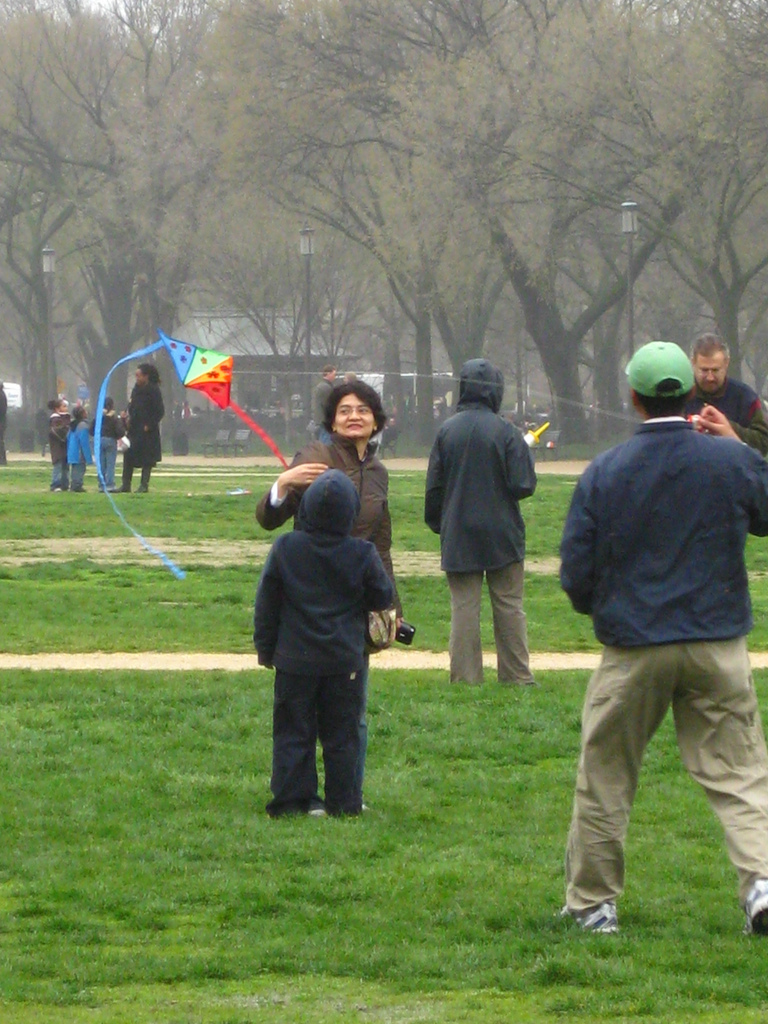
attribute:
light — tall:
[271, 184, 379, 415]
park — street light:
[271, 60, 737, 415]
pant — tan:
[504, 633, 750, 883]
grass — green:
[116, 687, 447, 1016]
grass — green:
[57, 706, 398, 930]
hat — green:
[594, 339, 758, 466]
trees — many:
[65, 50, 763, 290]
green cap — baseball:
[618, 327, 696, 407]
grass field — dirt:
[5, 462, 767, 1021]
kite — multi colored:
[83, 310, 287, 587]